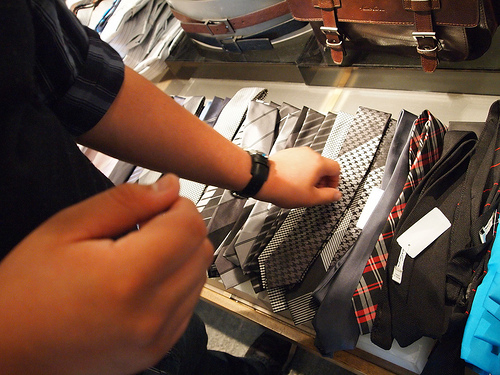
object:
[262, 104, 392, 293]
ties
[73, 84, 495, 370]
table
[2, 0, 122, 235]
shirt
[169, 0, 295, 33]
belt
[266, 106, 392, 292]
tie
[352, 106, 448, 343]
tie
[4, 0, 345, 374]
person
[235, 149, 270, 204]
watch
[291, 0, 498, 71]
bag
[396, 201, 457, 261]
tag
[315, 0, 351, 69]
belts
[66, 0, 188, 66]
shirts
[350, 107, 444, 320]
stripes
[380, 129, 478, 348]
tie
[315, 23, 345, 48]
buckle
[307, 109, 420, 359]
tie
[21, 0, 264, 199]
arm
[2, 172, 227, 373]
hand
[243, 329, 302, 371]
shoe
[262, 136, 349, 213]
hand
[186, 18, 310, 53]
belt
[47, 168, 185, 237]
thumb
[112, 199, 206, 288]
finger